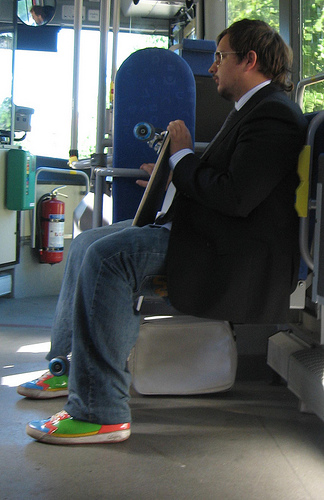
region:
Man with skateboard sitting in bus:
[14, 18, 308, 445]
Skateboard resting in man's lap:
[128, 120, 171, 228]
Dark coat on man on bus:
[166, 82, 304, 322]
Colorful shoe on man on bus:
[25, 408, 133, 445]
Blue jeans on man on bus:
[43, 212, 171, 423]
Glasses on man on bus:
[209, 48, 233, 64]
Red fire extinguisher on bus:
[33, 183, 69, 264]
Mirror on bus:
[14, 1, 63, 27]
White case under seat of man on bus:
[133, 312, 239, 396]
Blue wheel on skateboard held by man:
[130, 120, 155, 144]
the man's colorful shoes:
[19, 365, 132, 445]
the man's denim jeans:
[48, 209, 179, 422]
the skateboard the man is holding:
[118, 111, 170, 234]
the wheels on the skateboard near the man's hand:
[131, 121, 154, 139]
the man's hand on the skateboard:
[162, 115, 196, 155]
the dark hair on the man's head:
[219, 19, 290, 70]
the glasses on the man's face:
[211, 49, 238, 68]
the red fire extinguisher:
[35, 179, 68, 268]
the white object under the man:
[130, 309, 238, 400]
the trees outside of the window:
[231, 1, 268, 16]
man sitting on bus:
[174, 52, 310, 298]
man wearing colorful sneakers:
[34, 408, 111, 444]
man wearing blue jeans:
[92, 271, 116, 321]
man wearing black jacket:
[218, 194, 261, 261]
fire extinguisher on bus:
[39, 193, 76, 261]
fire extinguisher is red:
[43, 188, 79, 269]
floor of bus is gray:
[168, 448, 230, 485]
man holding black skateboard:
[132, 123, 178, 209]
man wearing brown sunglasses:
[209, 29, 226, 63]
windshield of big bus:
[42, 64, 73, 102]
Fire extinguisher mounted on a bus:
[5, 107, 67, 271]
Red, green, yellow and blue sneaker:
[22, 399, 147, 456]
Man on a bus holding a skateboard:
[104, 14, 310, 326]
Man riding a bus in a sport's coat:
[108, 9, 313, 333]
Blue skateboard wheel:
[125, 114, 162, 148]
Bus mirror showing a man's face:
[14, 0, 64, 38]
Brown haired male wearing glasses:
[198, 12, 302, 112]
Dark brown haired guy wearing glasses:
[207, 14, 300, 105]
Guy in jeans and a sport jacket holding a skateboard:
[8, 11, 307, 459]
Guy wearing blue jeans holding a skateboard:
[12, 13, 306, 446]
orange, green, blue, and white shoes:
[22, 404, 133, 446]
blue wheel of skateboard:
[46, 354, 71, 377]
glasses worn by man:
[212, 50, 251, 65]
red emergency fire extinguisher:
[27, 182, 71, 266]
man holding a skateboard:
[16, 17, 311, 445]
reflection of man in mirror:
[17, 0, 58, 24]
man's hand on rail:
[134, 159, 175, 192]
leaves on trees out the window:
[300, 0, 321, 80]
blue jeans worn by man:
[41, 212, 172, 427]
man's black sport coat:
[158, 83, 311, 326]